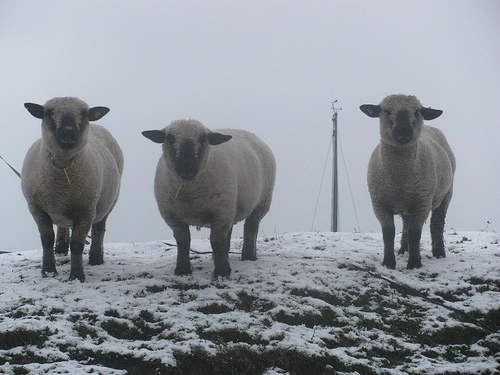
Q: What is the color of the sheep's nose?
A: Black.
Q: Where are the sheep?
A: On the snow.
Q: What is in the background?
A: Post.